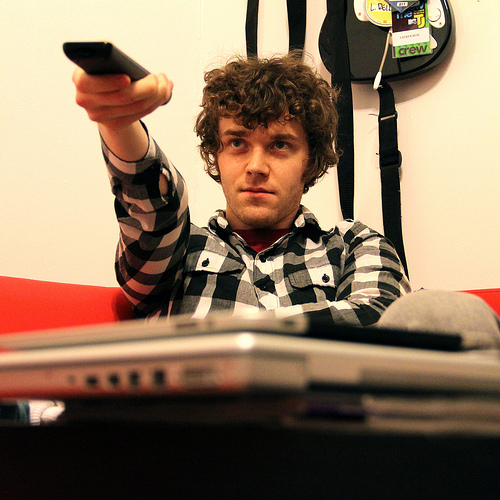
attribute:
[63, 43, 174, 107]
control — remote type, black, existing, a color, for tv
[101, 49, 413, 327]
man — sitting, here, pointing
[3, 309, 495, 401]
laptop — silver, closed, computer, in front, grey, a color, gray, black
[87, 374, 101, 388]
hole — black, on side of laptop, port, open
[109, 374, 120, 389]
hole — black, on side of laptop, port, open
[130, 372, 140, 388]
hole — black, on side of laptop, port, open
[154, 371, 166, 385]
hole — black, on side of laptop, port, open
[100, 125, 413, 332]
shirt — white, black, gray, checkered, being worn, flannel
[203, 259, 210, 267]
button — black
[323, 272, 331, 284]
button — black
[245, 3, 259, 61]
strap — black, hanging, down the wall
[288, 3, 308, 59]
strap — black, hanging, down the wall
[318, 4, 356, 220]
strap — black, hanging, down the wall, over the guitar, connected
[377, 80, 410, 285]
strap — black, hanging, down the wall, connected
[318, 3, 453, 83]
guitar — black, hanging, on top of wall, electric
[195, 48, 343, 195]
hair — laying, curly, brown, long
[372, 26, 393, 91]
bar — silver, white, hanging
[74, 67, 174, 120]
hand — holding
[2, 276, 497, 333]
couch — red, bright, orange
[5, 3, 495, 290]
wall — white, a color, off-white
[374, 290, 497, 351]
pants — gray, partially shown, grey, portion